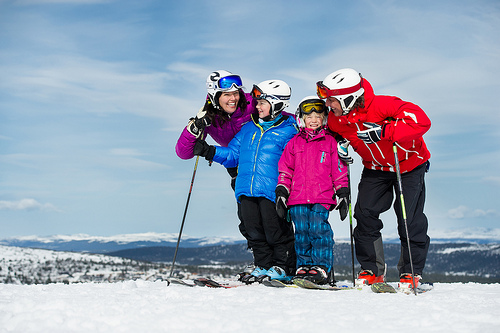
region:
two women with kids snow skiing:
[170, 69, 432, 289]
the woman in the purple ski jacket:
[166, 69, 253, 276]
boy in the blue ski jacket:
[196, 78, 290, 280]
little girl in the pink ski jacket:
[276, 97, 351, 283]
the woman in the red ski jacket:
[318, 68, 433, 284]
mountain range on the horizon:
[13, 233, 498, 260]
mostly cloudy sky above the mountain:
[2, 1, 498, 233]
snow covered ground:
[7, 279, 494, 331]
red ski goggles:
[315, 82, 361, 97]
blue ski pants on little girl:
[290, 204, 334, 275]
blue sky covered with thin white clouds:
[3, 5, 494, 238]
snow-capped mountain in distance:
[0, 227, 235, 242]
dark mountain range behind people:
[115, 240, 495, 272]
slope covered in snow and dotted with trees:
[2, 245, 147, 281]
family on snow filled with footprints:
[0, 280, 485, 325]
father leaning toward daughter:
[290, 66, 431, 291]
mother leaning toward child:
[191, 70, 282, 280]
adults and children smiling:
[205, 76, 345, 131]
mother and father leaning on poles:
[155, 66, 421, 291]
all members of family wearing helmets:
[186, 67, 367, 135]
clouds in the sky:
[19, 32, 144, 150]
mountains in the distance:
[16, 219, 164, 241]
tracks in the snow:
[66, 295, 468, 324]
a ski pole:
[174, 142, 186, 272]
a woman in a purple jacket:
[174, 80, 262, 161]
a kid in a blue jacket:
[219, 77, 299, 291]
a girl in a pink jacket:
[282, 99, 332, 279]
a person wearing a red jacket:
[321, 71, 426, 291]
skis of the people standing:
[167, 262, 423, 301]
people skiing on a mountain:
[180, 71, 440, 304]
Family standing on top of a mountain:
[165, 66, 438, 295]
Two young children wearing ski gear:
[233, 79, 340, 292]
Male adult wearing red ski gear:
[315, 67, 438, 294]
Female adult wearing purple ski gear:
[173, 68, 258, 161]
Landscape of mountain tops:
[2, 229, 498, 291]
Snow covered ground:
[0, 273, 496, 331]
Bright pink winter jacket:
[272, 127, 350, 210]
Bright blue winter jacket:
[212, 118, 298, 202]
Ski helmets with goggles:
[200, 66, 369, 131]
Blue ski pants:
[288, 201, 332, 273]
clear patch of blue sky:
[281, 0, 344, 42]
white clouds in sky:
[363, 2, 495, 65]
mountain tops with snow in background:
[0, 234, 156, 246]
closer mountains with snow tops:
[443, 240, 495, 271]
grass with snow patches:
[2, 248, 150, 281]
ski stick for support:
[169, 152, 201, 286]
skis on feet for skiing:
[181, 269, 431, 294]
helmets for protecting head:
[206, 68, 366, 126]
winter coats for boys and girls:
[222, 125, 338, 205]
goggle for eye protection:
[294, 99, 330, 114]